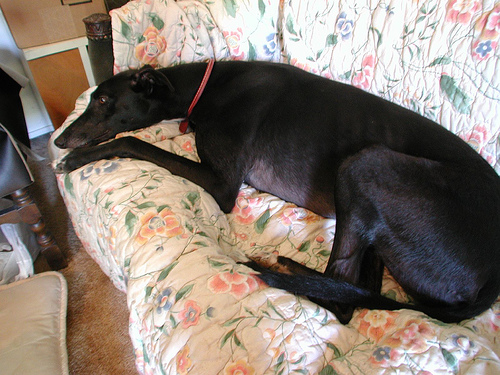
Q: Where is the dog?
A: On the couch.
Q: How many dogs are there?
A: One.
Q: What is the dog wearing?
A: A collar.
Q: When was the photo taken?
A: Daytime.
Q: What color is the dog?
A: Black.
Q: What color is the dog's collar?
A: Red.